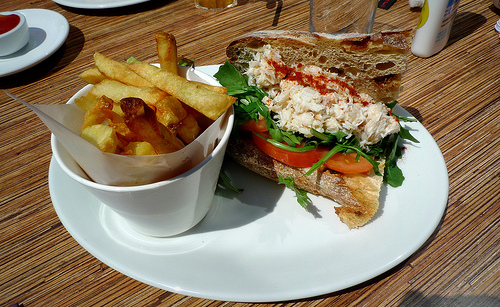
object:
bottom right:
[394, 264, 497, 307]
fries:
[127, 57, 236, 120]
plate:
[45, 63, 449, 305]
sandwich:
[224, 29, 419, 227]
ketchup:
[0, 16, 21, 35]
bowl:
[0, 13, 28, 56]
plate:
[0, 9, 69, 75]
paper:
[3, 89, 226, 187]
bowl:
[50, 64, 234, 237]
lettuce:
[214, 59, 418, 187]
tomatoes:
[250, 129, 338, 168]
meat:
[243, 42, 399, 151]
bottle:
[411, 0, 458, 58]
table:
[0, 0, 499, 305]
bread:
[227, 28, 415, 102]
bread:
[227, 135, 385, 229]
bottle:
[309, 0, 379, 34]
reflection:
[0, 28, 45, 60]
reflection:
[1, 24, 84, 88]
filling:
[214, 46, 418, 187]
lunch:
[75, 29, 419, 229]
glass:
[195, 0, 237, 10]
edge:
[410, 52, 429, 59]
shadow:
[398, 291, 499, 307]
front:
[77, 155, 219, 237]